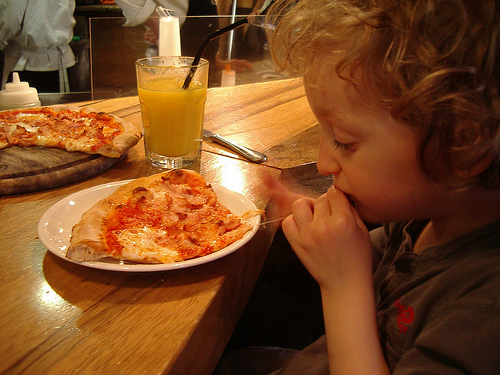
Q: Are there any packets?
A: No, there are no packets.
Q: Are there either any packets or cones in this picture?
A: No, there are no packets or cones.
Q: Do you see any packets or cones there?
A: No, there are no packets or cones.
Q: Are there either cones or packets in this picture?
A: No, there are no packets or cones.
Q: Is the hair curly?
A: Yes, the hair is curly.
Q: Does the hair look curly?
A: Yes, the hair is curly.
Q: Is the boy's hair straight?
A: No, the hair is curly.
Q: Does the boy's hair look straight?
A: No, the hair is curly.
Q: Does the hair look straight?
A: No, the hair is curly.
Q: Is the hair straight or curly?
A: The hair is curly.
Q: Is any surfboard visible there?
A: No, there are no surfboards.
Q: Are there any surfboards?
A: No, there are no surfboards.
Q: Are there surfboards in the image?
A: No, there are no surfboards.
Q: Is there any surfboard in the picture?
A: No, there are no surfboards.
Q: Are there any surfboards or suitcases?
A: No, there are no surfboards or suitcases.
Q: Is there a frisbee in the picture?
A: No, there are no frisbees.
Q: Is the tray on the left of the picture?
A: Yes, the tray is on the left of the image.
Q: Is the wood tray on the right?
A: No, the tray is on the left of the image.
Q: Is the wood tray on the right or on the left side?
A: The tray is on the left of the image.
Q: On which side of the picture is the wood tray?
A: The tray is on the left of the image.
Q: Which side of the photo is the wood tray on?
A: The tray is on the left of the image.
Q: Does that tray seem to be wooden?
A: Yes, the tray is wooden.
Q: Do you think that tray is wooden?
A: Yes, the tray is wooden.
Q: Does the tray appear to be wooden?
A: Yes, the tray is wooden.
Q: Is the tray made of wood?
A: Yes, the tray is made of wood.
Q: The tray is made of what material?
A: The tray is made of wood.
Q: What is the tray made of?
A: The tray is made of wood.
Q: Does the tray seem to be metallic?
A: No, the tray is wooden.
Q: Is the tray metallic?
A: No, the tray is wooden.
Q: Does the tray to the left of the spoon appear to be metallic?
A: No, the tray is wooden.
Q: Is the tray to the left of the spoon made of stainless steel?
A: No, the tray is made of wood.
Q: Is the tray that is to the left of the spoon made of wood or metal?
A: The tray is made of wood.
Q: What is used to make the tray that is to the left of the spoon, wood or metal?
A: The tray is made of wood.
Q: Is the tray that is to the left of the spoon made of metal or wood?
A: The tray is made of wood.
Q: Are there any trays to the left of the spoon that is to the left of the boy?
A: Yes, there is a tray to the left of the spoon.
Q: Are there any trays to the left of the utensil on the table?
A: Yes, there is a tray to the left of the spoon.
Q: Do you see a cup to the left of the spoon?
A: No, there is a tray to the left of the spoon.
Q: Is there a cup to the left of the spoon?
A: No, there is a tray to the left of the spoon.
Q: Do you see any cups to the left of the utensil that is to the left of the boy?
A: No, there is a tray to the left of the spoon.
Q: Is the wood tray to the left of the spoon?
A: Yes, the tray is to the left of the spoon.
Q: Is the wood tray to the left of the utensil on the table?
A: Yes, the tray is to the left of the spoon.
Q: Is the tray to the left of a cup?
A: No, the tray is to the left of the spoon.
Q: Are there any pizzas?
A: Yes, there is a pizza.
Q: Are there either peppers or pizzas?
A: Yes, there is a pizza.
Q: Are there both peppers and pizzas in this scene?
A: No, there is a pizza but no peppers.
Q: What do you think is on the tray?
A: The pizza is on the tray.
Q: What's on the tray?
A: The pizza is on the tray.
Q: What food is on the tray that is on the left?
A: The food is a pizza.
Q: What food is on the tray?
A: The food is a pizza.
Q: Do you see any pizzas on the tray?
A: Yes, there is a pizza on the tray.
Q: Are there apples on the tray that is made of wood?
A: No, there is a pizza on the tray.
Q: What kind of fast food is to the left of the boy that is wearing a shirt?
A: The food is a pizza.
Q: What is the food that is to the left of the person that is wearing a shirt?
A: The food is a pizza.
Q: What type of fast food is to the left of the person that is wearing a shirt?
A: The food is a pizza.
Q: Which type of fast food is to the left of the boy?
A: The food is a pizza.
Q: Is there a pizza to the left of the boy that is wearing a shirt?
A: Yes, there is a pizza to the left of the boy.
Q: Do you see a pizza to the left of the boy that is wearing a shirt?
A: Yes, there is a pizza to the left of the boy.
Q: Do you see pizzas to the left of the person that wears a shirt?
A: Yes, there is a pizza to the left of the boy.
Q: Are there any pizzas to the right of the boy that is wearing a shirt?
A: No, the pizza is to the left of the boy.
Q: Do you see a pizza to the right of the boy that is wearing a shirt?
A: No, the pizza is to the left of the boy.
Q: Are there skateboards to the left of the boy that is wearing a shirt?
A: No, there is a pizza to the left of the boy.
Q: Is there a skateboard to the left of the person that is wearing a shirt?
A: No, there is a pizza to the left of the boy.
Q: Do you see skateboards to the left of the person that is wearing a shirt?
A: No, there is a pizza to the left of the boy.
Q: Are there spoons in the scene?
A: Yes, there is a spoon.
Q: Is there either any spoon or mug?
A: Yes, there is a spoon.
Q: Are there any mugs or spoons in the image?
A: Yes, there is a spoon.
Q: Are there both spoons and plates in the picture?
A: Yes, there are both a spoon and a plate.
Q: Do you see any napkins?
A: No, there are no napkins.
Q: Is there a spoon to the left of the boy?
A: Yes, there is a spoon to the left of the boy.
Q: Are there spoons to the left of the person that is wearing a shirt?
A: Yes, there is a spoon to the left of the boy.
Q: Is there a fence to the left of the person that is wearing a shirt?
A: No, there is a spoon to the left of the boy.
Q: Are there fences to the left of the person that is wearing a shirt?
A: No, there is a spoon to the left of the boy.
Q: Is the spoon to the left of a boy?
A: Yes, the spoon is to the left of a boy.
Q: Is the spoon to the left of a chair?
A: No, the spoon is to the left of a boy.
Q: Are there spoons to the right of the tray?
A: Yes, there is a spoon to the right of the tray.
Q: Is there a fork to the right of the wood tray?
A: No, there is a spoon to the right of the tray.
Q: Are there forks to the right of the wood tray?
A: No, there is a spoon to the right of the tray.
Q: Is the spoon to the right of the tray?
A: Yes, the spoon is to the right of the tray.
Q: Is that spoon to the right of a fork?
A: No, the spoon is to the right of the tray.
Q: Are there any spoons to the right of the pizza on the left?
A: Yes, there is a spoon to the right of the pizza.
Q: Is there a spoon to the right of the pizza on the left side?
A: Yes, there is a spoon to the right of the pizza.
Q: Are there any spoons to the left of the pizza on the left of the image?
A: No, the spoon is to the right of the pizza.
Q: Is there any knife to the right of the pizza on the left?
A: No, there is a spoon to the right of the pizza.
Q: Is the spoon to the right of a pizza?
A: Yes, the spoon is to the right of a pizza.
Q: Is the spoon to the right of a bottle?
A: No, the spoon is to the right of a pizza.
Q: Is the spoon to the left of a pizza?
A: No, the spoon is to the right of a pizza.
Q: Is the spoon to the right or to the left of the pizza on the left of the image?
A: The spoon is to the right of the pizza.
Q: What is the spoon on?
A: The spoon is on the table.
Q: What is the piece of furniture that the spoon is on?
A: The piece of furniture is a table.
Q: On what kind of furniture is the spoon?
A: The spoon is on the table.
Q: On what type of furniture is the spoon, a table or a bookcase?
A: The spoon is on a table.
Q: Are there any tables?
A: Yes, there is a table.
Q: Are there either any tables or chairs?
A: Yes, there is a table.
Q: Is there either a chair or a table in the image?
A: Yes, there is a table.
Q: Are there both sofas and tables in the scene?
A: No, there is a table but no sofas.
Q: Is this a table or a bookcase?
A: This is a table.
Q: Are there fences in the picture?
A: No, there are no fences.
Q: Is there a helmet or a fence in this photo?
A: No, there are no fences or helmets.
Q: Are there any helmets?
A: No, there are no helmets.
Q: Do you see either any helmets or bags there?
A: No, there are no helmets or bags.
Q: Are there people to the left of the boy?
A: Yes, there is a person to the left of the boy.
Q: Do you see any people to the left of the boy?
A: Yes, there is a person to the left of the boy.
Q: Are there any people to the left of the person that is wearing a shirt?
A: Yes, there is a person to the left of the boy.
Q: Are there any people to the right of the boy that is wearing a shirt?
A: No, the person is to the left of the boy.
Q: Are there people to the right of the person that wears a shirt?
A: No, the person is to the left of the boy.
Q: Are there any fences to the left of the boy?
A: No, there is a person to the left of the boy.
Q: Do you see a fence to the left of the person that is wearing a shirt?
A: No, there is a person to the left of the boy.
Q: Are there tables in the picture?
A: Yes, there is a table.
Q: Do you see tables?
A: Yes, there is a table.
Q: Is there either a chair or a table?
A: Yes, there is a table.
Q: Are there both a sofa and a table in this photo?
A: No, there is a table but no sofas.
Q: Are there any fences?
A: No, there are no fences.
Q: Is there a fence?
A: No, there are no fences.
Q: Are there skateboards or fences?
A: No, there are no fences or skateboards.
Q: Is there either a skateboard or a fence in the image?
A: No, there are no fences or skateboards.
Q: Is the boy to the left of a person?
A: No, the boy is to the right of a person.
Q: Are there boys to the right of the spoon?
A: Yes, there is a boy to the right of the spoon.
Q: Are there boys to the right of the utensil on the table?
A: Yes, there is a boy to the right of the spoon.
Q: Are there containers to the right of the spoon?
A: No, there is a boy to the right of the spoon.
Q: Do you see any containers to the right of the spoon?
A: No, there is a boy to the right of the spoon.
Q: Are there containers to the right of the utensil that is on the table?
A: No, there is a boy to the right of the spoon.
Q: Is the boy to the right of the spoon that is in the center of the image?
A: Yes, the boy is to the right of the spoon.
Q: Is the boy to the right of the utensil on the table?
A: Yes, the boy is to the right of the spoon.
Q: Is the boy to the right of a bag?
A: No, the boy is to the right of the spoon.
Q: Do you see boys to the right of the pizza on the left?
A: Yes, there is a boy to the right of the pizza.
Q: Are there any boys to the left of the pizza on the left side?
A: No, the boy is to the right of the pizza.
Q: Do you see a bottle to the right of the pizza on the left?
A: No, there is a boy to the right of the pizza.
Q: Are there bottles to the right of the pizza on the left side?
A: No, there is a boy to the right of the pizza.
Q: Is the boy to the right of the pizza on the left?
A: Yes, the boy is to the right of the pizza.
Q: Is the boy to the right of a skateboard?
A: No, the boy is to the right of the pizza.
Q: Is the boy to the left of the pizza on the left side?
A: No, the boy is to the right of the pizza.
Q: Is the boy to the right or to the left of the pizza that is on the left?
A: The boy is to the right of the pizza.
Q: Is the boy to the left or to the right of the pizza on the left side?
A: The boy is to the right of the pizza.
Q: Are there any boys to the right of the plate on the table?
A: Yes, there is a boy to the right of the plate.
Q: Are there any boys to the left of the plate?
A: No, the boy is to the right of the plate.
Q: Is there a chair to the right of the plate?
A: No, there is a boy to the right of the plate.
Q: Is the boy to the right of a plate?
A: Yes, the boy is to the right of a plate.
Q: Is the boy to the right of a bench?
A: No, the boy is to the right of a plate.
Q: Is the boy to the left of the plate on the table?
A: No, the boy is to the right of the plate.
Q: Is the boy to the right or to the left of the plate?
A: The boy is to the right of the plate.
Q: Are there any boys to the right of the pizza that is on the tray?
A: Yes, there is a boy to the right of the pizza.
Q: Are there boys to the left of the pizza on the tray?
A: No, the boy is to the right of the pizza.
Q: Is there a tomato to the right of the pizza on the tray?
A: No, there is a boy to the right of the pizza.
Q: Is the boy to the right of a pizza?
A: Yes, the boy is to the right of a pizza.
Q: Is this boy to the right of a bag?
A: No, the boy is to the right of a pizza.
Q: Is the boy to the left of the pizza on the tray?
A: No, the boy is to the right of the pizza.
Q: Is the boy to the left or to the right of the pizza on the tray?
A: The boy is to the right of the pizza.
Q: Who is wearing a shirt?
A: The boy is wearing a shirt.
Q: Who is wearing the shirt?
A: The boy is wearing a shirt.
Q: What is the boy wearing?
A: The boy is wearing a shirt.